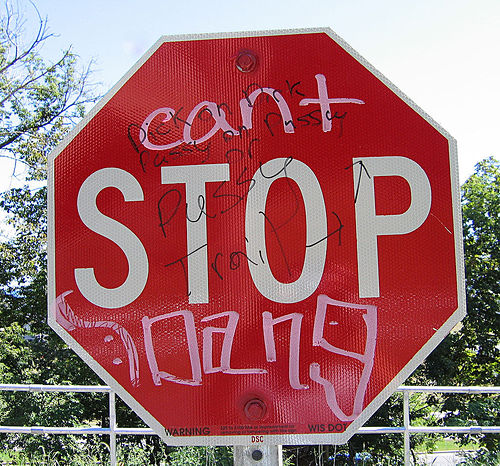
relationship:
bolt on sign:
[231, 394, 278, 431] [21, 35, 483, 451]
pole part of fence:
[230, 445, 282, 465] [1, 380, 499, 462]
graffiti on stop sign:
[117, 289, 382, 429] [25, 30, 463, 447]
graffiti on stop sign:
[258, 103, 352, 140] [33, 23, 474, 465]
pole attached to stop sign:
[230, 445, 282, 465] [33, 23, 474, 465]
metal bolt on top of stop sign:
[232, 50, 258, 76] [33, 23, 474, 465]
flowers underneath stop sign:
[330, 445, 374, 463] [33, 23, 474, 465]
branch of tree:
[1, 76, 40, 121] [0, 47, 62, 135]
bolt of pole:
[254, 435, 263, 463] [230, 442, 285, 464]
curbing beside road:
[411, 447, 478, 452] [408, 449, 480, 464]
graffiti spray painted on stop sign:
[138, 72, 365, 150] [25, 30, 463, 447]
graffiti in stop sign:
[117, 75, 380, 420] [33, 23, 474, 465]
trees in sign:
[470, 176, 498, 223] [65, 43, 407, 375]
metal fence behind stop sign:
[3, 381, 120, 464] [33, 23, 474, 465]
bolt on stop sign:
[234, 47, 255, 72] [33, 23, 474, 465]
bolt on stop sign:
[244, 399, 267, 420] [33, 23, 474, 465]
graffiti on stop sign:
[129, 119, 311, 299] [33, 23, 474, 465]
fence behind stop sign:
[1, 380, 499, 462] [33, 23, 474, 465]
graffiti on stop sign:
[341, 160, 375, 201] [33, 43, 496, 408]